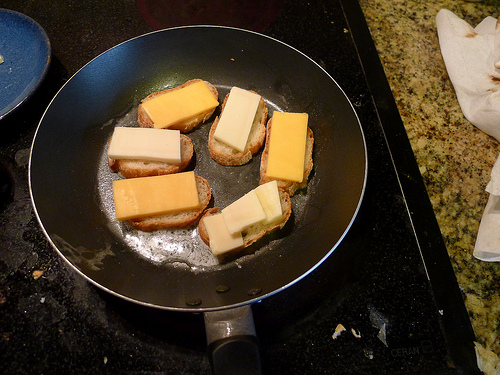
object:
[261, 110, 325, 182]
cheese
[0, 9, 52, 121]
plate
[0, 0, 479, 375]
stove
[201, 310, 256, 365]
handle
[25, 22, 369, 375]
pan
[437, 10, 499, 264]
towel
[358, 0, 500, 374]
counter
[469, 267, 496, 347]
granite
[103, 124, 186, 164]
cheese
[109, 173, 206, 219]
cheese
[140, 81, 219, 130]
cheese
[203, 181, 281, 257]
cheese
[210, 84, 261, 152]
cheese